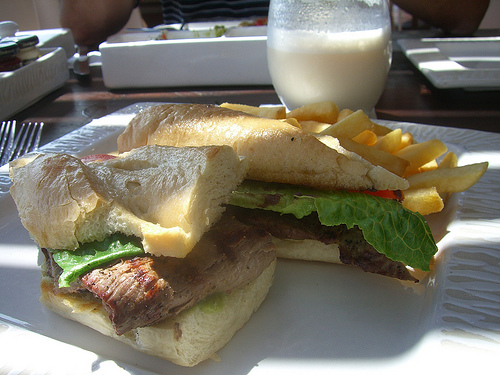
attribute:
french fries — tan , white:
[221, 101, 488, 214]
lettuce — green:
[45, 220, 150, 287]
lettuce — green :
[224, 182, 441, 277]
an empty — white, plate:
[401, 36, 497, 103]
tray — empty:
[98, 19, 273, 89]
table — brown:
[16, 40, 498, 172]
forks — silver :
[8, 97, 78, 214]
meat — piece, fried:
[21, 208, 312, 332]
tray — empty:
[397, 37, 499, 94]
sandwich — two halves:
[6, 102, 439, 367]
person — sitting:
[22, 68, 496, 128]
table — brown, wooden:
[10, 28, 499, 149]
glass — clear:
[264, 3, 394, 115]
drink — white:
[269, 28, 394, 119]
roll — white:
[10, 147, 254, 202]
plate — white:
[288, 273, 482, 358]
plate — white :
[0, 99, 498, 373]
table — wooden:
[31, 18, 428, 322]